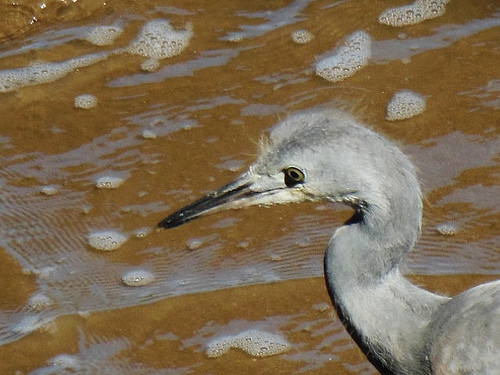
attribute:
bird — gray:
[155, 102, 499, 372]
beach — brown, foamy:
[2, 1, 499, 373]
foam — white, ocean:
[211, 331, 287, 352]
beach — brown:
[86, 251, 151, 323]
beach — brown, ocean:
[107, 291, 182, 339]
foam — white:
[87, 218, 148, 265]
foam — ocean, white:
[31, 162, 126, 201]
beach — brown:
[41, 224, 125, 309]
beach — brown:
[85, 76, 135, 116]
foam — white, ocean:
[117, 29, 184, 60]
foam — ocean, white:
[125, 25, 197, 72]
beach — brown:
[106, 81, 162, 137]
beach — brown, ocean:
[174, 50, 252, 104]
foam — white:
[123, 12, 186, 61]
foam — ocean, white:
[367, 71, 438, 139]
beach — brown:
[97, 119, 173, 164]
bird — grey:
[225, 76, 433, 366]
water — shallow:
[39, 168, 165, 324]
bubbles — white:
[65, 141, 121, 279]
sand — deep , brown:
[64, 159, 106, 240]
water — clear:
[87, 256, 195, 331]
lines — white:
[18, 230, 108, 317]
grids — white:
[50, 242, 150, 305]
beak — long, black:
[164, 189, 257, 233]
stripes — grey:
[205, 178, 275, 218]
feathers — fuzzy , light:
[275, 91, 410, 230]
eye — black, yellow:
[287, 163, 307, 190]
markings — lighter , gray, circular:
[383, 289, 478, 365]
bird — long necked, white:
[218, 81, 488, 370]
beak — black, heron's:
[171, 174, 280, 237]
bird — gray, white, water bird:
[211, 110, 457, 370]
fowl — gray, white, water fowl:
[190, 95, 437, 340]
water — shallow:
[107, 272, 206, 326]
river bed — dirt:
[56, 192, 147, 324]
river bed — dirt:
[94, 286, 226, 372]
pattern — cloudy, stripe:
[17, 209, 120, 296]